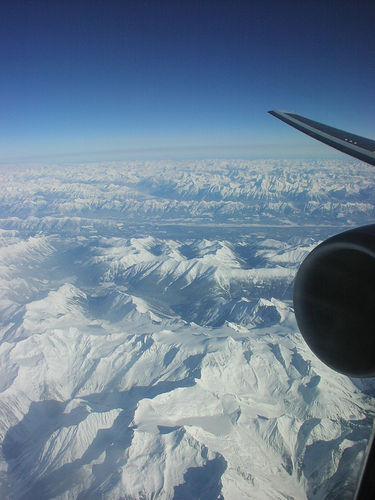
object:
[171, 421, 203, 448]
mountain peak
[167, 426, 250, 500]
snow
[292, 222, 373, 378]
engine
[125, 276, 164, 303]
dip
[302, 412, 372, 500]
shadow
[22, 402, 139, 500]
dark shadows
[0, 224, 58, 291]
mountains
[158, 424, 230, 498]
mountain peak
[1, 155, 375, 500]
snow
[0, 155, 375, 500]
mountain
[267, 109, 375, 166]
stripe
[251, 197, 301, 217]
mountains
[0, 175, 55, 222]
mountains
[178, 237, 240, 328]
mountains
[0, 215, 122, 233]
mountains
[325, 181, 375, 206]
mountains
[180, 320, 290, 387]
mountains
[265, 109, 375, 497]
airplane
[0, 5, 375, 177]
sky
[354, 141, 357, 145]
white mark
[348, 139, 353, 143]
white mark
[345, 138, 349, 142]
white mark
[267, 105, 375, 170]
plane's wing